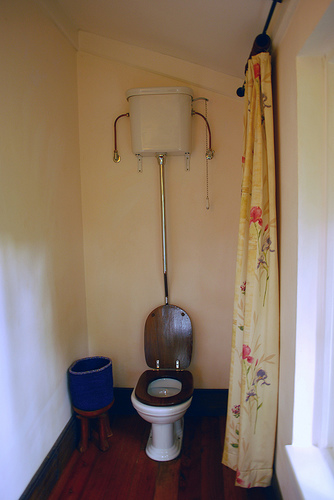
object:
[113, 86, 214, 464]
toilet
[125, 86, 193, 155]
tank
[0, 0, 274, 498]
wall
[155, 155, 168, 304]
pipe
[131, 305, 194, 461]
toilet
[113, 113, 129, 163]
pipe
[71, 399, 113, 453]
stool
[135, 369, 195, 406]
seat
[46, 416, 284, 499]
floor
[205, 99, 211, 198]
chain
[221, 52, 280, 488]
curtain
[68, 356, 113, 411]
basket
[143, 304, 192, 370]
lid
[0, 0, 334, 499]
bathroom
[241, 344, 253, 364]
flowers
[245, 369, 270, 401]
flower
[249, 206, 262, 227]
flower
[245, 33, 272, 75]
rings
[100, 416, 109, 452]
legs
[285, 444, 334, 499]
window sill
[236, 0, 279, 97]
curtain rod